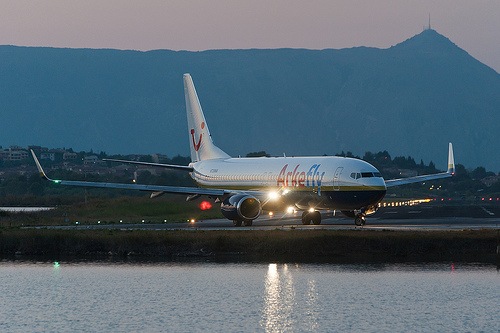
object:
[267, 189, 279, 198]
light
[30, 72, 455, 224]
plane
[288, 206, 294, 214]
light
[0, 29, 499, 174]
mountain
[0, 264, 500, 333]
water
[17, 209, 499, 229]
runway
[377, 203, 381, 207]
lights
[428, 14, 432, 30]
tower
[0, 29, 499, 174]
area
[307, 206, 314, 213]
headlights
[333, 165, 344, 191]
door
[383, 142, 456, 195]
wing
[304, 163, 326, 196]
words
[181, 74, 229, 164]
tail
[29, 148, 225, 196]
wing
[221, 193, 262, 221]
engine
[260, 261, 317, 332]
reflection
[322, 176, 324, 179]
windows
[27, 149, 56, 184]
wing tips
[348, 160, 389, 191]
cockpit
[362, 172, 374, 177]
windows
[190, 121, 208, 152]
logo